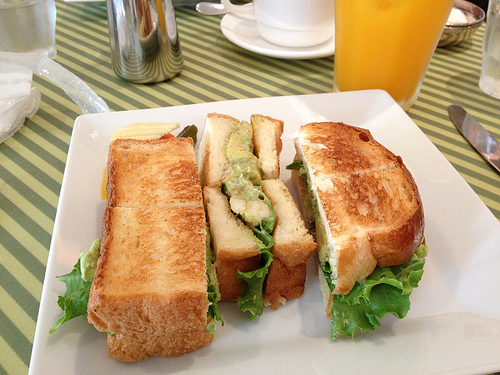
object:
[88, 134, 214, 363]
toast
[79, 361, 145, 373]
shadow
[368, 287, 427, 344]
lettuce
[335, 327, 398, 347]
shadow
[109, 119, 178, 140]
corn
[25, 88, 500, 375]
plate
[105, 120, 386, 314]
food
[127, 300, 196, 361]
crust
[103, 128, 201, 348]
bread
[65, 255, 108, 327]
iceberg lettuce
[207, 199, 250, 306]
bread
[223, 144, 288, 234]
chicken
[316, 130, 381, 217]
bread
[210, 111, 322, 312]
sandwich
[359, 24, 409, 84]
orange juice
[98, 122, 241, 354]
sandwich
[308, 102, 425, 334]
sandwich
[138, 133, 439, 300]
sandwich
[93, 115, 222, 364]
portions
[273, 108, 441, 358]
portions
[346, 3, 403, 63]
glass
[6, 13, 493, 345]
table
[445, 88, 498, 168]
knife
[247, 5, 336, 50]
cup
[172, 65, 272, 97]
cloth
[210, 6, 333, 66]
plate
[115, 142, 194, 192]
toasted bread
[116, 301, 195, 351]
sandwich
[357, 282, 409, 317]
lettuce